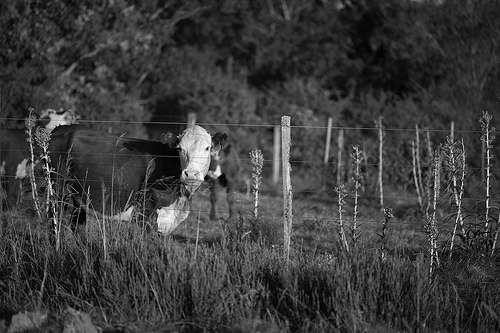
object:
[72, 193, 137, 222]
belly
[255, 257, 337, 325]
grass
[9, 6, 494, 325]
photo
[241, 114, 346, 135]
wire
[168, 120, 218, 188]
head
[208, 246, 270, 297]
grass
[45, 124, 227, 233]
cow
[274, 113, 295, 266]
post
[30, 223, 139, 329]
grass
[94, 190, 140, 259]
plants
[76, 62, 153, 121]
trees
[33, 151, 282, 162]
wires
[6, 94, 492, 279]
fence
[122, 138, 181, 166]
shadow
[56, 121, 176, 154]
back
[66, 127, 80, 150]
bone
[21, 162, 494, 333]
field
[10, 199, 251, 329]
bushes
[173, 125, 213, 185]
face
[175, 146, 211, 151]
eyes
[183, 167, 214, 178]
nose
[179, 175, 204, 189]
mouth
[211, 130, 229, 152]
ear